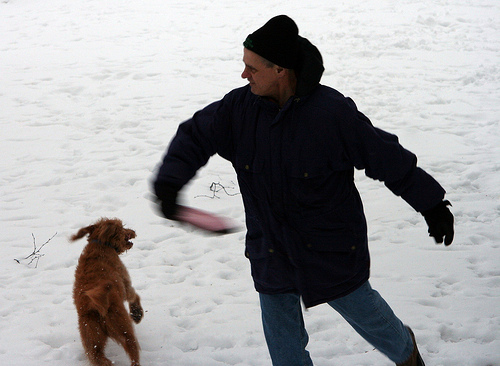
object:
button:
[266, 246, 273, 252]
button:
[241, 161, 251, 171]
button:
[351, 244, 358, 250]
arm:
[325, 89, 443, 219]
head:
[238, 14, 299, 96]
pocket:
[298, 229, 363, 291]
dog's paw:
[126, 301, 147, 323]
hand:
[418, 202, 457, 248]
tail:
[85, 285, 110, 319]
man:
[148, 13, 454, 366]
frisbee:
[171, 206, 244, 235]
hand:
[155, 197, 183, 223]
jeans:
[252, 278, 418, 366]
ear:
[275, 64, 290, 79]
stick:
[12, 230, 58, 271]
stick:
[188, 182, 239, 199]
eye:
[250, 65, 259, 73]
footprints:
[39, 73, 56, 84]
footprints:
[428, 291, 443, 300]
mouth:
[248, 78, 257, 87]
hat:
[241, 12, 308, 72]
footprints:
[484, 43, 500, 56]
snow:
[0, 0, 500, 365]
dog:
[68, 215, 143, 365]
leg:
[258, 292, 313, 365]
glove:
[424, 202, 456, 247]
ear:
[70, 224, 96, 242]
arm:
[156, 92, 235, 199]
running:
[69, 215, 153, 366]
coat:
[151, 80, 449, 309]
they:
[72, 12, 456, 365]